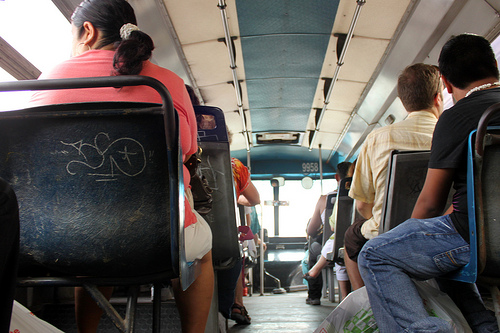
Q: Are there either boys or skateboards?
A: No, there are no boys or skateboards.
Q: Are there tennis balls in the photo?
A: No, there are no tennis balls.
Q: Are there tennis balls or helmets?
A: No, there are no tennis balls or helmets.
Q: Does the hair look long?
A: Yes, the hair is long.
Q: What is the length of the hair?
A: The hair is long.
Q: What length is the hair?
A: The hair is long.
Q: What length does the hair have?
A: The hair has long length.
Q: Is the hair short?
A: No, the hair is long.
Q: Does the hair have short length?
A: No, the hair is long.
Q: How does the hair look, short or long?
A: The hair is long.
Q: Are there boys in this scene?
A: No, there are no boys.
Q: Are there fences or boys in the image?
A: No, there are no boys or fences.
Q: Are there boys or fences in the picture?
A: No, there are no boys or fences.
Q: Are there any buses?
A: Yes, there is a bus.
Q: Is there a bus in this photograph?
A: Yes, there is a bus.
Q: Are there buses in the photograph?
A: Yes, there is a bus.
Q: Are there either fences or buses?
A: Yes, there is a bus.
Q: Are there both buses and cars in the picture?
A: No, there is a bus but no cars.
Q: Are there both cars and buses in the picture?
A: No, there is a bus but no cars.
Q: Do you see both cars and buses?
A: No, there is a bus but no cars.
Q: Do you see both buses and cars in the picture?
A: No, there is a bus but no cars.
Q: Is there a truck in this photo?
A: No, there are no trucks.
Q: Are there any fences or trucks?
A: No, there are no trucks or fences.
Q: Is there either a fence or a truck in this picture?
A: No, there are no trucks or fences.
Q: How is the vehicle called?
A: The vehicle is a bus.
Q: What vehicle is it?
A: The vehicle is a bus.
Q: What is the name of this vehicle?
A: This is a bus.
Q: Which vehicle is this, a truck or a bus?
A: This is a bus.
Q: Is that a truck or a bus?
A: That is a bus.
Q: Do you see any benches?
A: No, there are no benches.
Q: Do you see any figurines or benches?
A: No, there are no benches or figurines.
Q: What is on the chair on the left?
A: The graffiti is on the chair.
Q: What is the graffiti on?
A: The graffiti is on the chair.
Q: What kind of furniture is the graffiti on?
A: The graffiti is on the chair.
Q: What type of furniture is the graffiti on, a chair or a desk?
A: The graffiti is on a chair.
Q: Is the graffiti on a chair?
A: Yes, the graffiti is on a chair.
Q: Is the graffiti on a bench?
A: No, the graffiti is on a chair.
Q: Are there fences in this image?
A: No, there are no fences.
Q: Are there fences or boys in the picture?
A: No, there are no fences or boys.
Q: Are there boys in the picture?
A: No, there are no boys.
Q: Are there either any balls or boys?
A: No, there are no boys or balls.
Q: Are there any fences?
A: No, there are no fences.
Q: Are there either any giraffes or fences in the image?
A: No, there are no fences or giraffes.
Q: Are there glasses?
A: No, there are no glasses.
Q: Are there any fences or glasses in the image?
A: No, there are no glasses or fences.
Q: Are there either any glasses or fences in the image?
A: No, there are no glasses or fences.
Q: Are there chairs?
A: Yes, there is a chair.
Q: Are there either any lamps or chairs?
A: Yes, there is a chair.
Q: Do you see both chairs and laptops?
A: No, there is a chair but no laptops.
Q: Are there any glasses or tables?
A: No, there are no glasses or tables.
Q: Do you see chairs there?
A: Yes, there is a chair.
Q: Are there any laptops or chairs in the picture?
A: Yes, there is a chair.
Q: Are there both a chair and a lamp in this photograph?
A: No, there is a chair but no lamps.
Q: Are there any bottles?
A: No, there are no bottles.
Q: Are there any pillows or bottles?
A: No, there are no bottles or pillows.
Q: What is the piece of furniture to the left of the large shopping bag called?
A: The piece of furniture is a chair.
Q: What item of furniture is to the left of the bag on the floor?
A: The piece of furniture is a chair.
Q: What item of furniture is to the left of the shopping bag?
A: The piece of furniture is a chair.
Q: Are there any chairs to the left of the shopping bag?
A: Yes, there is a chair to the left of the shopping bag.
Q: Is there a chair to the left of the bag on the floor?
A: Yes, there is a chair to the left of the shopping bag.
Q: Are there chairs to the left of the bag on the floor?
A: Yes, there is a chair to the left of the shopping bag.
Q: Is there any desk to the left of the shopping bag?
A: No, there is a chair to the left of the shopping bag.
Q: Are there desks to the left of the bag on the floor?
A: No, there is a chair to the left of the shopping bag.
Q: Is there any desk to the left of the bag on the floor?
A: No, there is a chair to the left of the shopping bag.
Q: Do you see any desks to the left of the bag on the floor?
A: No, there is a chair to the left of the shopping bag.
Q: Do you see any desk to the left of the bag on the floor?
A: No, there is a chair to the left of the shopping bag.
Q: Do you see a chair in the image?
A: Yes, there is a chair.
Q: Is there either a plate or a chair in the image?
A: Yes, there is a chair.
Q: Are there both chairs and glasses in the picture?
A: No, there is a chair but no glasses.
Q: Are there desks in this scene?
A: No, there are no desks.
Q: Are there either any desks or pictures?
A: No, there are no desks or pictures.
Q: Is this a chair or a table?
A: This is a chair.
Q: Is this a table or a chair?
A: This is a chair.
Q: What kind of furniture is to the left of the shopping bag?
A: The piece of furniture is a chair.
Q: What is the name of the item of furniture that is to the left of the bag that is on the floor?
A: The piece of furniture is a chair.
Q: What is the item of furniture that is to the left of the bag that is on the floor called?
A: The piece of furniture is a chair.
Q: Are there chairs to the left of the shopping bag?
A: Yes, there is a chair to the left of the shopping bag.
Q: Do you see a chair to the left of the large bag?
A: Yes, there is a chair to the left of the shopping bag.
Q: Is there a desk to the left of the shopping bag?
A: No, there is a chair to the left of the shopping bag.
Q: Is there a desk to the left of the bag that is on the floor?
A: No, there is a chair to the left of the shopping bag.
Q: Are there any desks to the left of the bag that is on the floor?
A: No, there is a chair to the left of the shopping bag.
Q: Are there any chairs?
A: Yes, there is a chair.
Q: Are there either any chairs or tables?
A: Yes, there is a chair.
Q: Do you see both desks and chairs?
A: No, there is a chair but no desks.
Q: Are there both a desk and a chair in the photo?
A: No, there is a chair but no desks.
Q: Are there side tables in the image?
A: No, there are no side tables.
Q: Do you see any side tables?
A: No, there are no side tables.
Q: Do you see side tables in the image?
A: No, there are no side tables.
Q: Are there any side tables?
A: No, there are no side tables.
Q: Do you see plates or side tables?
A: No, there are no side tables or plates.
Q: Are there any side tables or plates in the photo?
A: No, there are no side tables or plates.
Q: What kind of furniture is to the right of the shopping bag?
A: The piece of furniture is a chair.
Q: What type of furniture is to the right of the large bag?
A: The piece of furniture is a chair.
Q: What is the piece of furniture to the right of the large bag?
A: The piece of furniture is a chair.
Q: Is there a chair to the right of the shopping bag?
A: Yes, there is a chair to the right of the shopping bag.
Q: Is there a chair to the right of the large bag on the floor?
A: Yes, there is a chair to the right of the shopping bag.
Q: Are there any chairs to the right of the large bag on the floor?
A: Yes, there is a chair to the right of the shopping bag.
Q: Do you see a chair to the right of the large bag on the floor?
A: Yes, there is a chair to the right of the shopping bag.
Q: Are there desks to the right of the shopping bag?
A: No, there is a chair to the right of the shopping bag.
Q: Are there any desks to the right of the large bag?
A: No, there is a chair to the right of the shopping bag.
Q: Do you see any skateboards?
A: No, there are no skateboards.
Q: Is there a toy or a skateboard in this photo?
A: No, there are no skateboards or toys.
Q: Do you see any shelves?
A: No, there are no shelves.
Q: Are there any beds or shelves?
A: No, there are no shelves or beds.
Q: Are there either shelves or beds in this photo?
A: No, there are no shelves or beds.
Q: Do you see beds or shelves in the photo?
A: No, there are no shelves or beds.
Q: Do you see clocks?
A: No, there are no clocks.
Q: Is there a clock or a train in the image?
A: No, there are no clocks or trains.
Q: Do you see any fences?
A: No, there are no fences.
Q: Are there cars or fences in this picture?
A: No, there are no fences or cars.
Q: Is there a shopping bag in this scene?
A: Yes, there is a shopping bag.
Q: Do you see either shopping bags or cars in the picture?
A: Yes, there is a shopping bag.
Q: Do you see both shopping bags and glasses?
A: No, there is a shopping bag but no glasses.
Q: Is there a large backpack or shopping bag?
A: Yes, there is a large shopping bag.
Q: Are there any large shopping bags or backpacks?
A: Yes, there is a large shopping bag.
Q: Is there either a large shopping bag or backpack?
A: Yes, there is a large shopping bag.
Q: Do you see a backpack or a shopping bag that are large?
A: Yes, the shopping bag is large.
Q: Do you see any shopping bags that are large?
A: Yes, there is a large shopping bag.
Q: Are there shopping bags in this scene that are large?
A: Yes, there is a shopping bag that is large.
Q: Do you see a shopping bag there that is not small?
A: Yes, there is a large shopping bag.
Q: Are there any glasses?
A: No, there are no glasses.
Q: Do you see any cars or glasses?
A: No, there are no glasses or cars.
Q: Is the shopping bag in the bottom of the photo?
A: Yes, the shopping bag is in the bottom of the image.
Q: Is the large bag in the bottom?
A: Yes, the shopping bag is in the bottom of the image.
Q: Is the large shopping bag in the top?
A: No, the shopping bag is in the bottom of the image.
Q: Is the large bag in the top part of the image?
A: No, the shopping bag is in the bottom of the image.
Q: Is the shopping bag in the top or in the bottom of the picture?
A: The shopping bag is in the bottom of the image.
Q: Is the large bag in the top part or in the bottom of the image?
A: The shopping bag is in the bottom of the image.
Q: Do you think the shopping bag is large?
A: Yes, the shopping bag is large.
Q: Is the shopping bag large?
A: Yes, the shopping bag is large.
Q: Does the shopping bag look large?
A: Yes, the shopping bag is large.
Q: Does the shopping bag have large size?
A: Yes, the shopping bag is large.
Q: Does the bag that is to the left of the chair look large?
A: Yes, the shopping bag is large.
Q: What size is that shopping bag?
A: The shopping bag is large.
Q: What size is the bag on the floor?
A: The shopping bag is large.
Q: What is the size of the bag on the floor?
A: The shopping bag is large.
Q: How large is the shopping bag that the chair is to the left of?
A: The shopping bag is large.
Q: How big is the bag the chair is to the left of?
A: The shopping bag is large.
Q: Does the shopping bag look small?
A: No, the shopping bag is large.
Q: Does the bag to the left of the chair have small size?
A: No, the shopping bag is large.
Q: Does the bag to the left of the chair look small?
A: No, the shopping bag is large.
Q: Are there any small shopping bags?
A: No, there is a shopping bag but it is large.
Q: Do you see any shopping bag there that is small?
A: No, there is a shopping bag but it is large.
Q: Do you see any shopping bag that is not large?
A: No, there is a shopping bag but it is large.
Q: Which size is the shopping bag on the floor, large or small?
A: The shopping bag is large.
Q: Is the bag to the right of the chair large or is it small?
A: The shopping bag is large.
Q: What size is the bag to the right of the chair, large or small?
A: The shopping bag is large.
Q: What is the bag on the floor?
A: The bag is a shopping bag.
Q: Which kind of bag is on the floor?
A: The bag is a shopping bag.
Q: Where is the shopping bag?
A: The shopping bag is on the floor.